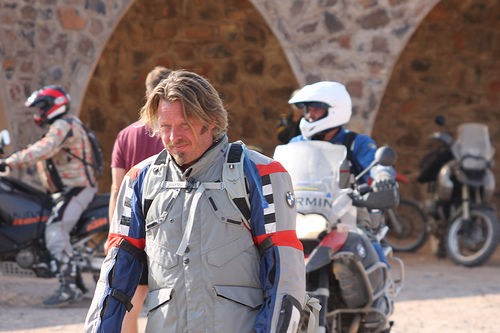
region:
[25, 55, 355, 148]
Two peole are wearing helmet.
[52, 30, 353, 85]
wall is brown color.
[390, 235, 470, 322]
Shadow falls on ground.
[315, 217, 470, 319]
ground is brown color.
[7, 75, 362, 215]
Five people are in front of the wall.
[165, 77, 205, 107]
Hair is brown color.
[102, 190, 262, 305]
Jacket is grey and blue color.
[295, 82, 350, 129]
Helmet is white color.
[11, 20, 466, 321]
Day time picture.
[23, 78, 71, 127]
helmet is black and red color.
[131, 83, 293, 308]
this is a man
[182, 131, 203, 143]
the man is light skinned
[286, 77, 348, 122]
this is a helmet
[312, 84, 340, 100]
the helmet is white in color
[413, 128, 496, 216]
this is a motorbike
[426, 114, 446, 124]
this is a mirror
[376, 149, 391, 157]
the mirrotr is black in color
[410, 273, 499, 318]
this is the road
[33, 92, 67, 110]
the helmet is red in color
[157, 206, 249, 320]
this is a jacket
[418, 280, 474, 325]
this is the ground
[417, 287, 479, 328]
the ground is made of stone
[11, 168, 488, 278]
these are some motorcycles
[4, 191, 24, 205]
the motorcycle is black in color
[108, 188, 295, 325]
this is a jacket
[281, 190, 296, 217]
this is a BMW logo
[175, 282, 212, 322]
the jacket is grey in color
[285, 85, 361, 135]
this is a helmet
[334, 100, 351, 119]
the helmet is white in color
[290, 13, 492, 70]
this is a structure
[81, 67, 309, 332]
A man with short hair walking with a mostly gray outfit on.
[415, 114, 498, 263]
Gray motorcycle parked with the front wheel tilted to the right.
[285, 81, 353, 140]
White helmet on a man looking to the left.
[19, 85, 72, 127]
Red black and white helmet on a man's head.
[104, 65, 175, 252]
Guy standing in a maroon colored shirt.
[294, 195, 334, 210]
The letters RMIN on a man's windshield.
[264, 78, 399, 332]
Guy on a motorcycle who is wearing a white helmet.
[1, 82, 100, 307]
Guy on a motorcycle wearing a red, white and black helmet.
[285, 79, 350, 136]
White helmet on a man riding a bike.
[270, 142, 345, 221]
Windshield on a bike in front of a man with a white helmet.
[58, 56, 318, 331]
man looking toward the camera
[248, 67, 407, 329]
rider with a white helmet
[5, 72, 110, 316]
rider with a red and black helmet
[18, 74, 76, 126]
red and black bike helmet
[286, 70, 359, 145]
white bike helmet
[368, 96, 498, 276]
bike standing alone near the wall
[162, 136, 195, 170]
blond man's facial hair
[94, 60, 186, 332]
person in a maroon shirt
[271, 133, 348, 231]
windshield on bike ridden by man with white helmet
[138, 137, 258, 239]
shoulder straps of backpack of blond man